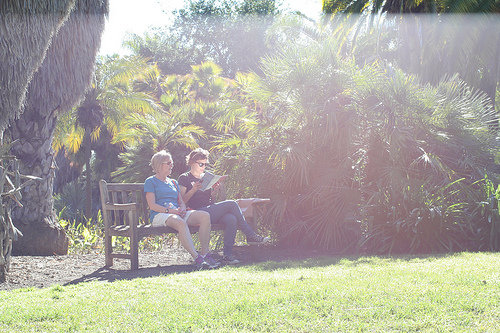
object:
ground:
[0, 225, 499, 332]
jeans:
[200, 200, 260, 257]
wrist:
[161, 206, 172, 214]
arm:
[143, 179, 177, 214]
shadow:
[61, 241, 462, 287]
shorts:
[151, 209, 199, 227]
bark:
[3, 108, 61, 230]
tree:
[0, 0, 110, 257]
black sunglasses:
[189, 159, 210, 168]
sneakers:
[195, 258, 220, 271]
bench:
[97, 178, 259, 272]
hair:
[148, 149, 174, 175]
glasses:
[162, 161, 174, 166]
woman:
[142, 149, 221, 270]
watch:
[165, 208, 170, 214]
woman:
[177, 147, 272, 265]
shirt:
[177, 170, 213, 211]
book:
[197, 171, 229, 193]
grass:
[0, 249, 499, 331]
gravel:
[0, 241, 357, 289]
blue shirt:
[143, 174, 182, 227]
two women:
[142, 148, 270, 270]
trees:
[316, 0, 499, 133]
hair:
[185, 147, 210, 168]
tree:
[0, 0, 76, 284]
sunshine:
[0, 0, 499, 332]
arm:
[107, 202, 140, 270]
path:
[0, 237, 308, 293]